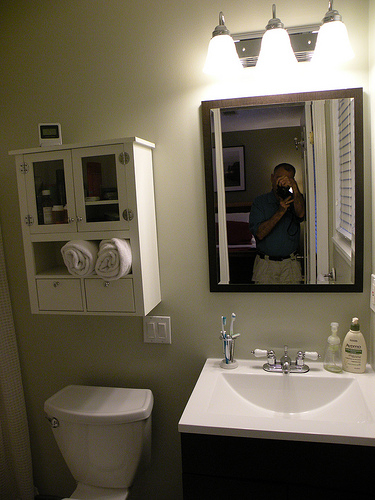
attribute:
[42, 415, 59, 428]
handle — metal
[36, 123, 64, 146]
clock — small, white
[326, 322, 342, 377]
bottle — clear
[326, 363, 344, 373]
soap — hand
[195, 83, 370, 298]
mirror — hung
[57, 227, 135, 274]
towel — rolled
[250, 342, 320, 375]
metal faucet — sink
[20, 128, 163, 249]
cabinet — attached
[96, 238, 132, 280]
towel — rolled-up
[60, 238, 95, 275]
towel — rolled-up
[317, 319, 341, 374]
bottle — plastic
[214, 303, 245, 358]
brushes — tooth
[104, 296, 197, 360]
switches — white, light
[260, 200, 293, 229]
arm — tattooed, man's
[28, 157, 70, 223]
glass window — small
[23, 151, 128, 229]
glass window — small